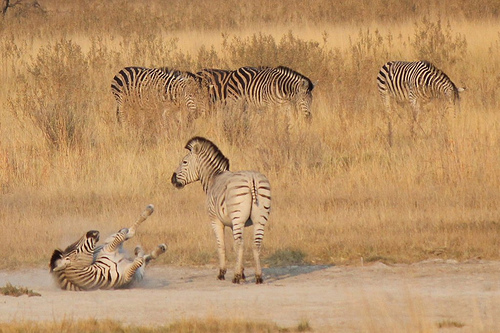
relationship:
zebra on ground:
[179, 142, 285, 269] [8, 11, 472, 231]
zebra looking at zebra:
[179, 142, 285, 269] [48, 207, 179, 291]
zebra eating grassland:
[179, 142, 285, 269] [269, 127, 500, 256]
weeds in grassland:
[281, 117, 452, 180] [269, 127, 500, 256]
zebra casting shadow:
[179, 142, 285, 269] [267, 233, 321, 271]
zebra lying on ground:
[48, 207, 179, 291] [8, 11, 472, 231]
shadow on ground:
[267, 233, 321, 271] [8, 11, 472, 231]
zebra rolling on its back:
[48, 207, 179, 291] [59, 273, 181, 291]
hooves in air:
[115, 208, 171, 253] [101, 175, 174, 223]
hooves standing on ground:
[211, 261, 269, 280] [8, 11, 472, 231]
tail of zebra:
[252, 190, 263, 205] [179, 142, 285, 269]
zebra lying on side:
[48, 207, 179, 291] [26, 266, 178, 305]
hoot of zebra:
[211, 261, 269, 280] [179, 142, 285, 269]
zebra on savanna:
[179, 142, 285, 269] [8, 11, 472, 231]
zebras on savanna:
[125, 56, 293, 98] [8, 11, 472, 231]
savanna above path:
[8, 11, 472, 231] [0, 260, 500, 333]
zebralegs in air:
[115, 208, 171, 253] [101, 175, 174, 223]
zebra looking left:
[179, 142, 285, 269] [5, 3, 59, 324]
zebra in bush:
[179, 142, 285, 269] [8, 11, 472, 231]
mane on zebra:
[426, 62, 449, 78] [373, 56, 478, 128]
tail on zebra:
[252, 190, 263, 205] [373, 56, 478, 128]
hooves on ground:
[211, 261, 269, 280] [8, 11, 472, 231]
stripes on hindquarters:
[230, 174, 248, 214] [222, 173, 272, 251]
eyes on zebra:
[185, 156, 189, 165] [179, 142, 285, 269]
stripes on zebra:
[230, 174, 248, 214] [179, 142, 285, 269]